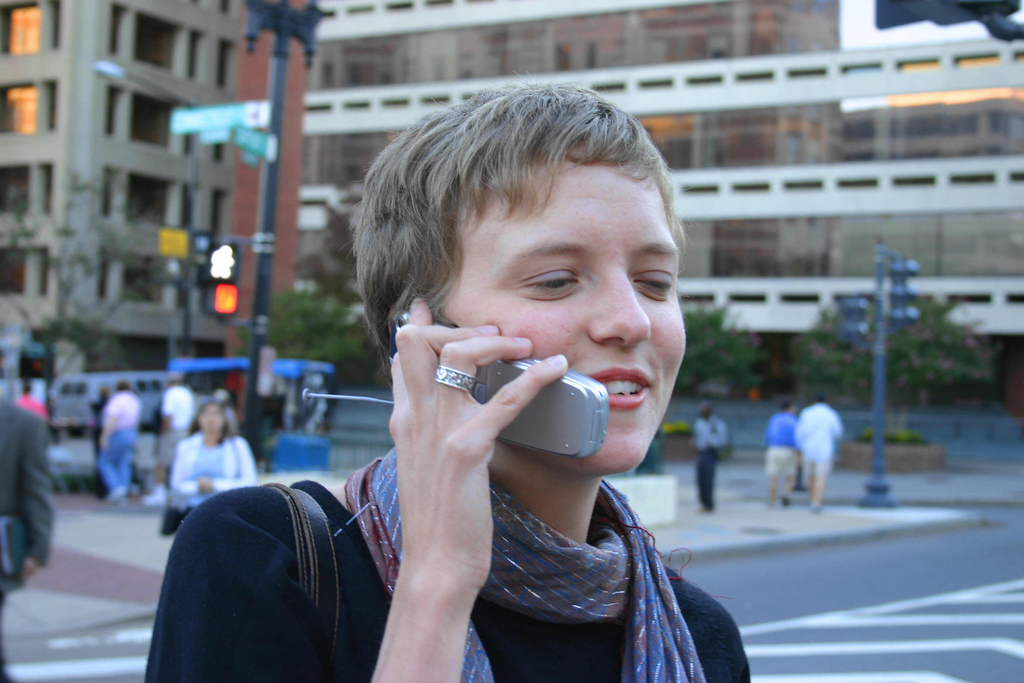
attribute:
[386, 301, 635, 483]
cell phone — silver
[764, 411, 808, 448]
shirt — blue  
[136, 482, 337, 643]
sleeves — long 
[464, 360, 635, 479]
cellphone — flip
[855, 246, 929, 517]
pole. — black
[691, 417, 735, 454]
shirt — grey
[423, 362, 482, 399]
ring — silver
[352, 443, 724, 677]
scarf — worn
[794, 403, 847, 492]
shirt — white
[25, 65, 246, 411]
building — large, light, grey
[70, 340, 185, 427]
bus — grey